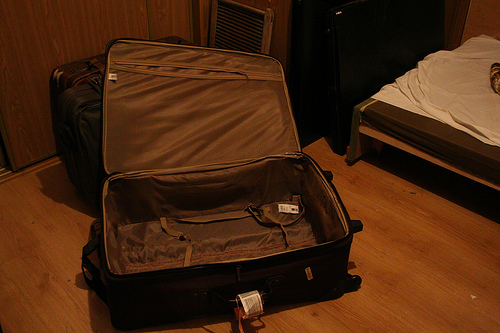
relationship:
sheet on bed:
[370, 25, 499, 154] [343, 32, 499, 207]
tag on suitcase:
[240, 291, 264, 320] [99, 55, 241, 322]